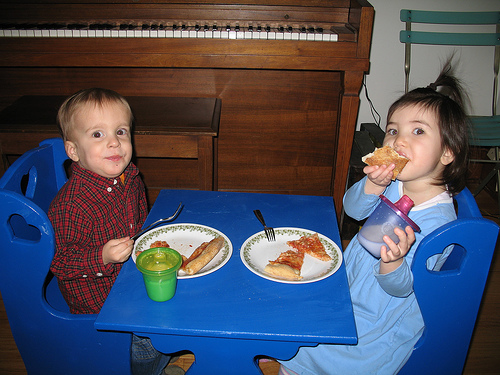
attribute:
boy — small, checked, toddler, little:
[47, 84, 156, 312]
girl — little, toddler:
[275, 89, 455, 371]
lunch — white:
[241, 220, 344, 285]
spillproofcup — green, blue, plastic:
[126, 244, 191, 303]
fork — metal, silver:
[251, 203, 279, 241]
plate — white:
[242, 229, 346, 279]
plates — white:
[129, 211, 346, 295]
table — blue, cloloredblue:
[96, 180, 359, 359]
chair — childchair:
[0, 139, 57, 374]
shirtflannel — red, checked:
[47, 166, 139, 316]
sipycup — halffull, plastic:
[362, 187, 418, 262]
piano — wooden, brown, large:
[4, 6, 377, 193]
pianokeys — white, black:
[6, 23, 345, 44]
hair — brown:
[55, 89, 145, 130]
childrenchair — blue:
[413, 214, 499, 374]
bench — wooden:
[5, 90, 217, 190]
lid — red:
[376, 187, 426, 235]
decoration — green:
[249, 235, 260, 256]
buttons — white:
[81, 272, 107, 281]